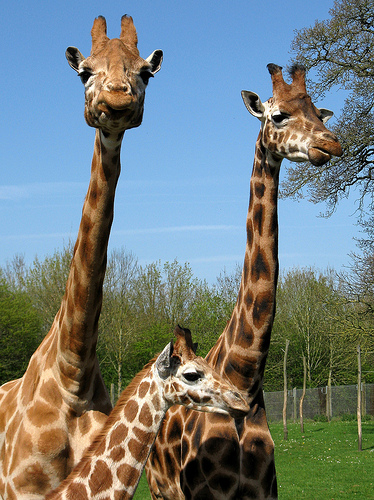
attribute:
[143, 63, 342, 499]
giraffe — adult, looking away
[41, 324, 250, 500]
giraffe — young, small, looking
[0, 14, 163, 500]
giraffe — adult, looking at us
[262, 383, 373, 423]
fence — chain link, retaining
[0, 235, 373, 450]
wooded area — green, distant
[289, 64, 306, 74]
tip — black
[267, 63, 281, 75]
tip — black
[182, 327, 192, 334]
tip — black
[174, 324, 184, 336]
tip — black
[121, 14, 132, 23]
tip — black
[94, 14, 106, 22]
tip — black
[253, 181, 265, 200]
marking — orange, black, brown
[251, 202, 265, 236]
marking — orange, black, brown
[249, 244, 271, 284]
marking — orange, black, brown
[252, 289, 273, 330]
marking — orange, black, brown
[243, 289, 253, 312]
marking — orange, black, brown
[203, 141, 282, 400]
neck — long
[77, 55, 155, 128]
face — snarling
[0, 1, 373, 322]
sky — clear, blue, light blue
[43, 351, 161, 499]
mane — orange-brown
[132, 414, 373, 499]
grass — green, lush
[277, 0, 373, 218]
tree — green